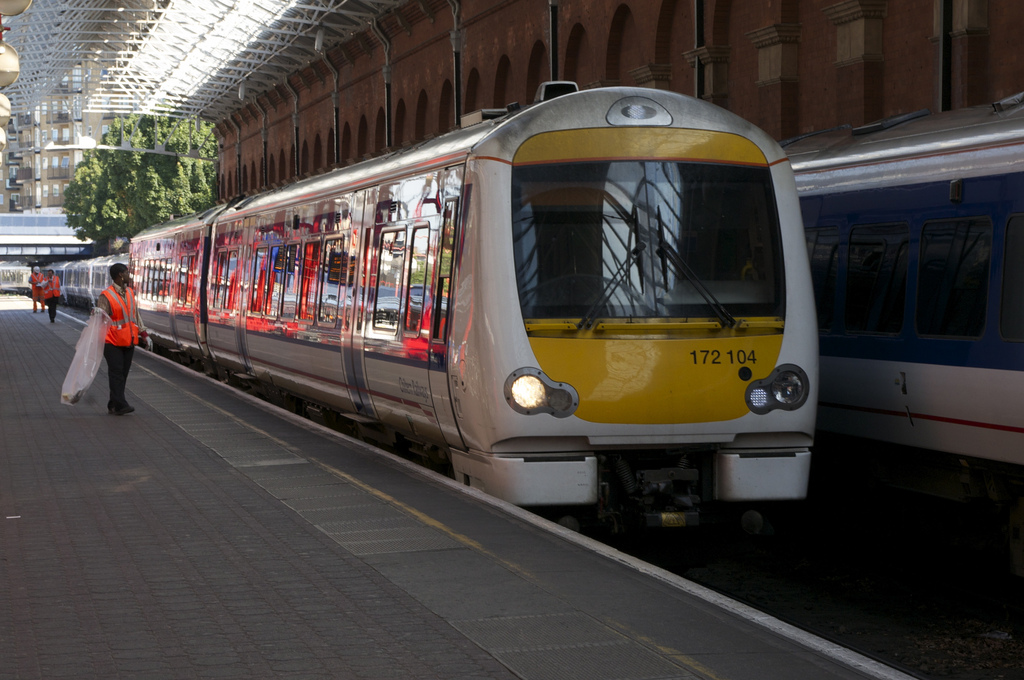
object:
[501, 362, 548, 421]
headlight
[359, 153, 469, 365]
reflection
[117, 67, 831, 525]
train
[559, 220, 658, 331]
wiper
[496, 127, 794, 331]
windshield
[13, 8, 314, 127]
ceiling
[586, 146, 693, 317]
reflection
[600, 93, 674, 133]
headlight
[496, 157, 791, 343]
window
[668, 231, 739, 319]
wipers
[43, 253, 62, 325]
worker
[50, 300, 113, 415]
bag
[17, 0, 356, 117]
roof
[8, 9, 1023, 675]
station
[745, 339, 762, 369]
number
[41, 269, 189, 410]
man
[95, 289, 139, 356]
safety vest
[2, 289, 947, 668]
station platform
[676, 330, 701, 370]
identification numbers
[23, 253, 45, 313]
worker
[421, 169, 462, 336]
windows